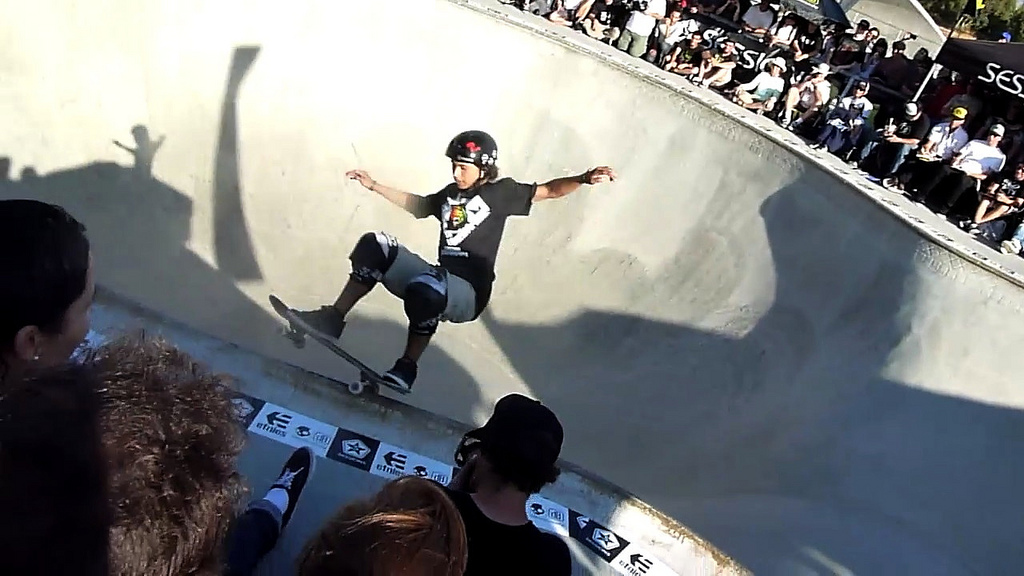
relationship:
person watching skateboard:
[852, 98, 932, 181] [242, 282, 414, 401]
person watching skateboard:
[928, 95, 967, 219] [242, 282, 414, 401]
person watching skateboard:
[430, 388, 574, 575] [242, 282, 414, 401]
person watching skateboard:
[736, 55, 789, 116] [242, 282, 414, 401]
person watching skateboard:
[955, 96, 1013, 227] [242, 282, 414, 401]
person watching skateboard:
[5, 174, 97, 380] [242, 282, 414, 401]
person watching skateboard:
[430, 388, 574, 572] [263, 285, 412, 400]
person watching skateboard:
[301, 473, 476, 574] [249, 279, 422, 403]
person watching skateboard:
[63, 332, 289, 567] [248, 273, 439, 392]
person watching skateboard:
[430, 388, 574, 572] [259, 280, 430, 405]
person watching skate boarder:
[430, 388, 574, 575] [268, 118, 613, 403]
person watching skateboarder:
[888, 107, 967, 194] [259, 115, 616, 405]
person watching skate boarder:
[811, 81, 876, 152] [268, 118, 613, 403]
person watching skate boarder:
[0, 192, 97, 380] [268, 118, 613, 403]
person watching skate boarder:
[0, 341, 264, 575] [268, 118, 613, 403]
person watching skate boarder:
[301, 473, 476, 574] [268, 118, 613, 403]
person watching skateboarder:
[811, 81, 876, 152] [271, 130, 613, 394]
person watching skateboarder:
[0, 192, 97, 380] [271, 130, 613, 394]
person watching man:
[430, 388, 574, 575] [284, 132, 610, 394]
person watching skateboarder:
[301, 473, 476, 574] [230, 143, 674, 393]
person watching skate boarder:
[301, 473, 476, 574] [251, 78, 647, 418]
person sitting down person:
[430, 388, 574, 575] [266, 119, 620, 405]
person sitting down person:
[301, 473, 469, 572] [266, 119, 620, 405]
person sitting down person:
[0, 341, 264, 575] [266, 119, 620, 405]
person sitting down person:
[0, 192, 97, 380] [266, 119, 620, 405]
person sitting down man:
[735, 52, 787, 119] [284, 132, 610, 394]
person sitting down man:
[811, 81, 875, 152] [284, 132, 610, 394]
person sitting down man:
[861, 98, 923, 188] [284, 132, 610, 394]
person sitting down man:
[888, 107, 967, 194] [284, 132, 610, 394]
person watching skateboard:
[852, 98, 932, 181] [258, 282, 429, 385]